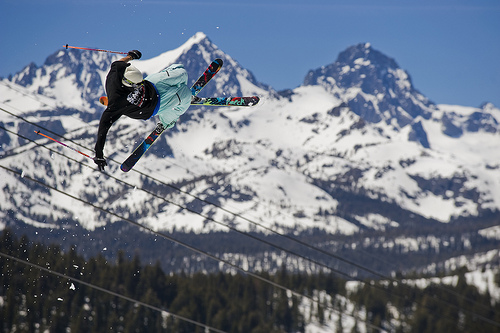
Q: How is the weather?
A: It is clear.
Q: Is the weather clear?
A: Yes, it is clear.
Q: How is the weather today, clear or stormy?
A: It is clear.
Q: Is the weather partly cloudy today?
A: No, it is clear.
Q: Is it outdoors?
A: Yes, it is outdoors.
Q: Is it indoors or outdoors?
A: It is outdoors.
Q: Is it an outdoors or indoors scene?
A: It is outdoors.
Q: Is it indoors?
A: No, it is outdoors.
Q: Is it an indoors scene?
A: No, it is outdoors.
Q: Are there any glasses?
A: No, there are no glasses.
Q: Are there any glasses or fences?
A: No, there are no glasses or fences.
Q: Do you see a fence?
A: No, there are no fences.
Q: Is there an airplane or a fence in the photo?
A: No, there are no fences or airplanes.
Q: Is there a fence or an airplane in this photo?
A: No, there are no fences or airplanes.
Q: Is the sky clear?
A: Yes, the sky is clear.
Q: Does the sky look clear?
A: Yes, the sky is clear.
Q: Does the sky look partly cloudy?
A: No, the sky is clear.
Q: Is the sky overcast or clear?
A: The sky is clear.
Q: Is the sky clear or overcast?
A: The sky is clear.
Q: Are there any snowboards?
A: No, there are no snowboards.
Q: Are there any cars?
A: No, there are no cars.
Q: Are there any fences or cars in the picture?
A: No, there are no cars or fences.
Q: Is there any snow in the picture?
A: Yes, there is snow.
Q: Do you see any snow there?
A: Yes, there is snow.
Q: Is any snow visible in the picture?
A: Yes, there is snow.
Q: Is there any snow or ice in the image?
A: Yes, there is snow.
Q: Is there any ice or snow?
A: Yes, there is snow.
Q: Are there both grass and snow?
A: No, there is snow but no grass.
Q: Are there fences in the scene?
A: No, there are no fences.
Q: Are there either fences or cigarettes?
A: No, there are no fences or cigarettes.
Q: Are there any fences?
A: No, there are no fences.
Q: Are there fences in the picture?
A: No, there are no fences.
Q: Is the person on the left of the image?
A: Yes, the person is on the left of the image.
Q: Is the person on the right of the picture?
A: No, the person is on the left of the image.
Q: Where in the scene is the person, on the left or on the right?
A: The person is on the left of the image.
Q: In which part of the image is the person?
A: The person is on the left of the image.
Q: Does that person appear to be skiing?
A: Yes, the person is skiing.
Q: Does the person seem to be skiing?
A: Yes, the person is skiing.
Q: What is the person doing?
A: The person is skiing.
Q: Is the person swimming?
A: No, the person is skiing.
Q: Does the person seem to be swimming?
A: No, the person is skiing.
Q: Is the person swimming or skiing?
A: The person is skiing.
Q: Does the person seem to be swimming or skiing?
A: The person is skiing.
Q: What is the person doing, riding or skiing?
A: The person is skiing.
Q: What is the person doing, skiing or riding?
A: The person is skiing.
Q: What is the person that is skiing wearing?
A: The person is wearing pants.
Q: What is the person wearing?
A: The person is wearing pants.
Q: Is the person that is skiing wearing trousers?
A: Yes, the person is wearing trousers.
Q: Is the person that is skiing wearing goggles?
A: No, the person is wearing trousers.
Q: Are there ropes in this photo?
A: No, there are no ropes.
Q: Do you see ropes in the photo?
A: No, there are no ropes.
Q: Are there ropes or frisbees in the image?
A: No, there are no ropes or frisbees.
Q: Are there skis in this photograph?
A: Yes, there are skis.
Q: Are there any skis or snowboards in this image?
A: Yes, there are skis.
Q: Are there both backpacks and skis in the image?
A: No, there are skis but no backpacks.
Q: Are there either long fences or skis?
A: Yes, there are long skis.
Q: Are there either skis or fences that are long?
A: Yes, the skis are long.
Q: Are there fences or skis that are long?
A: Yes, the skis are long.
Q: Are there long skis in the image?
A: Yes, there are long skis.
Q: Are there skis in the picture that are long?
A: Yes, there are skis that are long.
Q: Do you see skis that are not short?
A: Yes, there are long skis.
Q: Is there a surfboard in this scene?
A: No, there are no surfboards.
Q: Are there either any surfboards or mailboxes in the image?
A: No, there are no surfboards or mailboxes.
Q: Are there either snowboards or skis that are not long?
A: No, there are skis but they are long.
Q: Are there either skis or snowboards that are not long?
A: No, there are skis but they are long.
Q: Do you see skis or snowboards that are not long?
A: No, there are skis but they are long.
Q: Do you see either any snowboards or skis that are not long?
A: No, there are skis but they are long.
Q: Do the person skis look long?
A: Yes, the skis are long.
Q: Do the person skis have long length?
A: Yes, the skis are long.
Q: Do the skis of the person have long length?
A: Yes, the skis are long.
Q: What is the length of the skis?
A: The skis are long.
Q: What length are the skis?
A: The skis are long.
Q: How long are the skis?
A: The skis are long.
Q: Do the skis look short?
A: No, the skis are long.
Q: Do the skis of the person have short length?
A: No, the skis are long.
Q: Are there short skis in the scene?
A: No, there are skis but they are long.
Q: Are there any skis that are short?
A: No, there are skis but they are long.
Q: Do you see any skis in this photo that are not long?
A: No, there are skis but they are long.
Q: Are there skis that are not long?
A: No, there are skis but they are long.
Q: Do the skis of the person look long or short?
A: The skis are long.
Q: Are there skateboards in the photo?
A: No, there are no skateboards.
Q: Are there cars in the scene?
A: No, there are no cars.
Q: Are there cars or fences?
A: No, there are no cars or fences.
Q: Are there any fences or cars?
A: No, there are no cars or fences.